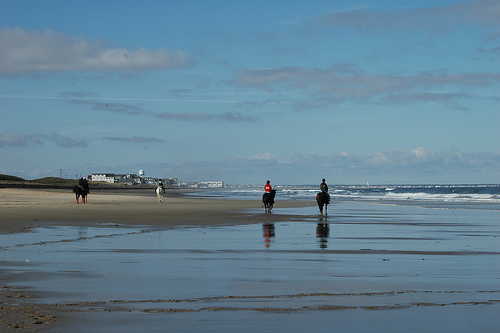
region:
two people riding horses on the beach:
[263, 175, 330, 219]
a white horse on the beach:
[155, 184, 168, 201]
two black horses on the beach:
[261, 188, 331, 218]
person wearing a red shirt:
[263, 181, 272, 194]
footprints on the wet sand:
[1, 285, 56, 331]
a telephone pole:
[56, 165, 65, 177]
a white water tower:
[137, 168, 147, 184]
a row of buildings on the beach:
[92, 173, 224, 186]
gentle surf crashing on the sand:
[380, 188, 498, 204]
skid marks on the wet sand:
[59, 288, 496, 316]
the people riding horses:
[56, 170, 361, 221]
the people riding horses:
[53, 150, 413, 246]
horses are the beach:
[26, 147, 354, 248]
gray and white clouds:
[38, 48, 260, 148]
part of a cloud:
[313, 70, 352, 97]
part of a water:
[346, 226, 401, 280]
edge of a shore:
[127, 200, 187, 252]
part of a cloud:
[340, 53, 384, 93]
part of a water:
[379, 208, 431, 256]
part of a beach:
[124, 195, 161, 217]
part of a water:
[211, 249, 253, 280]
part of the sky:
[353, 116, 388, 148]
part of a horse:
[261, 192, 279, 209]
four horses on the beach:
[69, 174, 332, 214]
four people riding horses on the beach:
[70, 165, 337, 216]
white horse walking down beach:
[151, 178, 171, 203]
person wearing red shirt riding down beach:
[261, 179, 282, 209]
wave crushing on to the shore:
[288, 183, 495, 208]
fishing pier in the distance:
[237, 179, 497, 195]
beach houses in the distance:
[82, 164, 229, 194]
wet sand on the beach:
[33, 184, 489, 329]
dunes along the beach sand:
[1, 164, 196, 191]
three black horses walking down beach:
[68, 168, 333, 212]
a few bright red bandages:
[75, 196, 85, 203]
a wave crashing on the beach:
[366, 188, 486, 211]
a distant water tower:
[138, 165, 148, 185]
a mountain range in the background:
[225, 140, 498, 192]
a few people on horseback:
[251, 174, 344, 216]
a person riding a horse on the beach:
[150, 176, 171, 204]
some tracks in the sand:
[116, 260, 474, 319]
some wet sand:
[119, 227, 497, 327]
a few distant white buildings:
[90, 168, 180, 188]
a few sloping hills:
[1, 170, 86, 187]